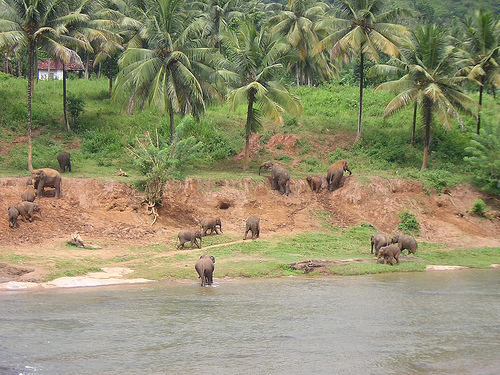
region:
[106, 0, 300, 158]
two tropical palm trees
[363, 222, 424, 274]
group of three elephants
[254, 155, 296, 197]
elephant climbing up a bank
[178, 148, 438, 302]
a herd of elephants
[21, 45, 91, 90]
house with a red roof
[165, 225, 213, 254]
elephant walking along a path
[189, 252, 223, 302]
back of elephant in water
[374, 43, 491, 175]
tree and green foliage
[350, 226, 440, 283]
elephants along a shoreline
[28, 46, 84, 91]
white house red roof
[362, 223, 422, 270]
Three elephants standing in the grass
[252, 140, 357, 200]
Two elephants walking up a hill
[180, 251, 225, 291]
An elephant standing in the water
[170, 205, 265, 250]
Three elephants walking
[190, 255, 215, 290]
The back of an elephant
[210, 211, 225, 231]
The head of an elephant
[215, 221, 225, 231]
The trunk of an elephant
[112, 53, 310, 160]
Two palm trees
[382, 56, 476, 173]
A single palm tree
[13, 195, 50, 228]
A baby elephant on a hill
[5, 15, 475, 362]
A herd of elephants is together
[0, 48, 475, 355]
The elephants are enjoying the water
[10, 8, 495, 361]
The elephants are in the tropics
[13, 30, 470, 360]
The elephants are looking for food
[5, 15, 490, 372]
Many elephants are walking around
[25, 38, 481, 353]
The elephants are out in daytime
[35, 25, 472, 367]
The elephants are enjoying the day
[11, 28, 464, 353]
An elephant is getting wet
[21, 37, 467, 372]
Some elephants are climbing a hill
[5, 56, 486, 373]
The elephants are teaching their young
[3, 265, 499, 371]
Brown colored water.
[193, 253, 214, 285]
Back end of a brown elephant half in the water.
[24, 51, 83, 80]
A white house with red roof.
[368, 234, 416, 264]
Three brown elephants down by the water.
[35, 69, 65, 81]
White side of the house under the red roof.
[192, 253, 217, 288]
Back end of a brown elephant in the water.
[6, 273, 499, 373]
Brown murky water.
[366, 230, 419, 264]
Three brown elephants near the water on the right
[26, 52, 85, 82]
White house with red roof through the trees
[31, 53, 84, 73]
Red roof on a white house through the trees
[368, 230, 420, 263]
Three elephants standing by each other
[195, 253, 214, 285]
An elephant in the water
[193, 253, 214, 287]
A brown elephant outside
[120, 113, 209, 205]
A big shrub growing outside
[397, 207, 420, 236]
A wild plant outside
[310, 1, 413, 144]
A giant palm tree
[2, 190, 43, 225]
Baby elephants outside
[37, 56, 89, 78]
A house by a lake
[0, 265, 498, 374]
A lake that is flowing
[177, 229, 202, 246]
A dark colored elephant